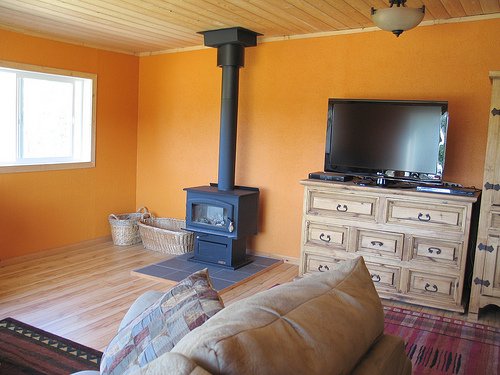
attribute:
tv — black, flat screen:
[322, 96, 459, 187]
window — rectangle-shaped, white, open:
[2, 60, 99, 176]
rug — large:
[382, 304, 484, 370]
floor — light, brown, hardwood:
[2, 244, 482, 373]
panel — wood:
[297, 3, 346, 56]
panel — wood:
[151, 4, 230, 38]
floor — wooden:
[3, 233, 473, 372]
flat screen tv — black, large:
[325, 98, 446, 189]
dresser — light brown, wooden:
[303, 180, 479, 314]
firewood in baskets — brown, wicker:
[107, 208, 195, 255]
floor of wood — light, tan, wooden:
[0, 245, 155, 350]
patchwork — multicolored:
[96, 267, 223, 373]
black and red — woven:
[381, 305, 498, 373]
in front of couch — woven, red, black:
[0, 313, 110, 373]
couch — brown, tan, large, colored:
[97, 257, 410, 372]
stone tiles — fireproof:
[131, 251, 283, 292]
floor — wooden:
[1, 247, 133, 319]